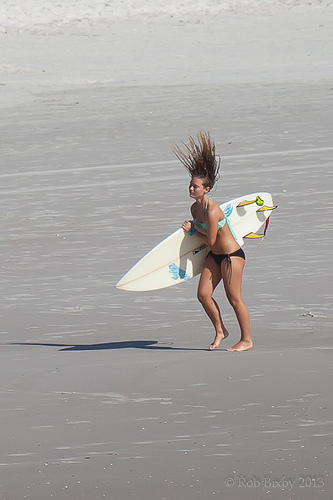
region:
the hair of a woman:
[176, 123, 220, 175]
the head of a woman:
[179, 172, 208, 202]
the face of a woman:
[188, 176, 205, 195]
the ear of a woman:
[199, 181, 214, 195]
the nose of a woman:
[186, 184, 197, 192]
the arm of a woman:
[200, 210, 223, 249]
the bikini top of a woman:
[189, 215, 228, 234]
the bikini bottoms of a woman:
[206, 245, 269, 268]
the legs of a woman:
[186, 261, 254, 326]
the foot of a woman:
[217, 327, 258, 361]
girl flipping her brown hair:
[165, 124, 225, 205]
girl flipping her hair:
[171, 129, 222, 201]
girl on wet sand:
[162, 129, 291, 406]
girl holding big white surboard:
[102, 151, 321, 405]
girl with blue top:
[110, 121, 277, 353]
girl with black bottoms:
[149, 140, 294, 382]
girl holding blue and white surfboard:
[148, 123, 281, 364]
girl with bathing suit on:
[127, 123, 281, 372]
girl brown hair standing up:
[129, 123, 272, 342]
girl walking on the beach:
[138, 107, 294, 379]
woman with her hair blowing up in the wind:
[172, 133, 220, 195]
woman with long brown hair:
[173, 131, 221, 198]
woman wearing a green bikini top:
[188, 201, 235, 240]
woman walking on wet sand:
[171, 131, 253, 351]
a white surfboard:
[114, 191, 272, 289]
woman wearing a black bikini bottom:
[207, 248, 245, 284]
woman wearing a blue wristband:
[189, 228, 195, 235]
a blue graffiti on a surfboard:
[170, 263, 189, 281]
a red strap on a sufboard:
[263, 215, 269, 238]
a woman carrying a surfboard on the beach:
[116, 131, 278, 353]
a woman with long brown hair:
[137, 121, 253, 213]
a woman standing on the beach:
[113, 133, 285, 414]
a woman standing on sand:
[124, 146, 315, 482]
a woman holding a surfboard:
[108, 137, 296, 387]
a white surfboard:
[113, 177, 302, 298]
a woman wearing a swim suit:
[150, 171, 292, 335]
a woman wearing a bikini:
[184, 172, 261, 307]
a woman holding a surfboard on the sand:
[121, 146, 304, 490]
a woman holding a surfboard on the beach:
[148, 133, 289, 393]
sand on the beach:
[24, 406, 228, 494]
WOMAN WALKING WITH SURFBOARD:
[107, 127, 278, 354]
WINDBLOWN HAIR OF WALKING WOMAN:
[170, 134, 224, 177]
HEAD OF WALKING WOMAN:
[187, 175, 217, 198]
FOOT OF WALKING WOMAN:
[207, 328, 230, 353]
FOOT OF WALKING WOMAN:
[224, 339, 257, 352]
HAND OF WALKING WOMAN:
[181, 219, 195, 236]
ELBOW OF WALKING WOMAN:
[203, 236, 216, 249]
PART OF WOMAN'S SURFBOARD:
[232, 202, 260, 228]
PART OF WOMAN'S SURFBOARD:
[129, 268, 153, 285]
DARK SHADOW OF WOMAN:
[76, 335, 127, 354]